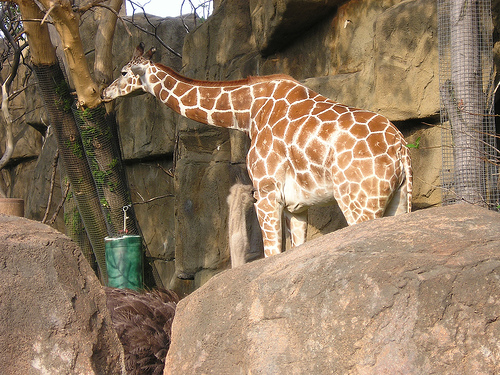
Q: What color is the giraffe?
A: Brown/white.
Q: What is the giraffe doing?
A: Standing on a rock.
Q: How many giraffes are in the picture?
A: One.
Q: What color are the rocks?
A: Gray.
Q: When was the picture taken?
A: In the daytime.